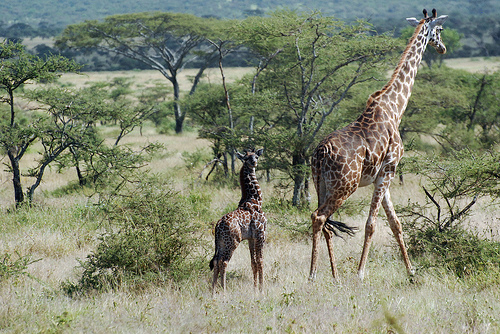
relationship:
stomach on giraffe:
[357, 170, 379, 188] [305, 7, 447, 291]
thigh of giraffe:
[378, 183, 386, 215] [305, 7, 447, 291]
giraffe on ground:
[305, 7, 447, 291] [2, 63, 499, 334]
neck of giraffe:
[378, 30, 431, 116] [305, 7, 447, 291]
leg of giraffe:
[356, 172, 396, 274] [305, 7, 447, 291]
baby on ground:
[207, 147, 268, 294] [2, 63, 499, 334]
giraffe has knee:
[305, 7, 447, 291] [389, 215, 403, 235]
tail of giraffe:
[315, 148, 361, 239] [305, 7, 447, 291]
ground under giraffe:
[2, 63, 499, 334] [305, 7, 447, 291]